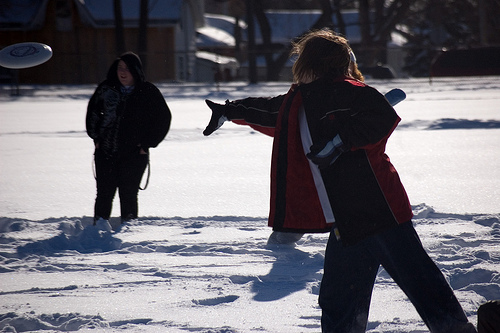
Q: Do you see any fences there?
A: No, there are no fences.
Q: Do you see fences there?
A: No, there are no fences.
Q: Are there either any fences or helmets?
A: No, there are no fences or helmets.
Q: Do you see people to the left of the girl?
A: Yes, there is a person to the left of the girl.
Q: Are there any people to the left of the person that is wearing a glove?
A: Yes, there is a person to the left of the girl.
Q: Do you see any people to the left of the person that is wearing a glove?
A: Yes, there is a person to the left of the girl.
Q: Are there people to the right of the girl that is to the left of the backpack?
A: No, the person is to the left of the girl.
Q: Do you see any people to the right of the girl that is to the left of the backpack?
A: No, the person is to the left of the girl.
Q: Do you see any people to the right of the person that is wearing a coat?
A: No, the person is to the left of the girl.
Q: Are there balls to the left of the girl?
A: No, there is a person to the left of the girl.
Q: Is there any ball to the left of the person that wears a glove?
A: No, there is a person to the left of the girl.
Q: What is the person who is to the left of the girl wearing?
A: The person is wearing trousers.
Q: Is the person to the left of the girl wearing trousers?
A: Yes, the person is wearing trousers.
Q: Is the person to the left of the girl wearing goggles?
A: No, the person is wearing trousers.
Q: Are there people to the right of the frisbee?
A: Yes, there is a person to the right of the frisbee.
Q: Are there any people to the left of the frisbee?
A: No, the person is to the right of the frisbee.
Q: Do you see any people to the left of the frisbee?
A: No, the person is to the right of the frisbee.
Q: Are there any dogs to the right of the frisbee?
A: No, there is a person to the right of the frisbee.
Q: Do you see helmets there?
A: No, there are no helmets.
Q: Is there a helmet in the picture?
A: No, there are no helmets.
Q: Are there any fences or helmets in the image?
A: No, there are no helmets or fences.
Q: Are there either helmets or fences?
A: No, there are no helmets or fences.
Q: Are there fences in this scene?
A: No, there are no fences.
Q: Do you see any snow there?
A: Yes, there is snow.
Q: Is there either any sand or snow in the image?
A: Yes, there is snow.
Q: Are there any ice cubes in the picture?
A: No, there are no ice cubes.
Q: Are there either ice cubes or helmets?
A: No, there are no ice cubes or helmets.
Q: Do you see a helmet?
A: No, there are no helmets.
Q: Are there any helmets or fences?
A: No, there are no helmets or fences.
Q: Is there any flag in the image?
A: No, there are no flags.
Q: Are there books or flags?
A: No, there are no flags or books.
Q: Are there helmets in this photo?
A: No, there are no helmets.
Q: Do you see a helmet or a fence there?
A: No, there are no helmets or fences.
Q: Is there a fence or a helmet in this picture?
A: No, there are no helmets or fences.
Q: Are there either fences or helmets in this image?
A: No, there are no helmets or fences.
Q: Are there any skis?
A: No, there are no skis.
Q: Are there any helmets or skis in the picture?
A: No, there are no skis or helmets.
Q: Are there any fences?
A: No, there are no fences.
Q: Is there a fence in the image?
A: No, there are no fences.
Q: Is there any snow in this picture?
A: Yes, there is snow.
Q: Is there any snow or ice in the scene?
A: Yes, there is snow.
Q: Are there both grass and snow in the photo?
A: No, there is snow but no grass.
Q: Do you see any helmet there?
A: No, there are no helmets.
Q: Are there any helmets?
A: No, there are no helmets.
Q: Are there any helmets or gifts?
A: No, there are no helmets or gifts.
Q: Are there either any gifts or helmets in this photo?
A: No, there are no helmets or gifts.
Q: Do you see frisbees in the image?
A: Yes, there is a frisbee.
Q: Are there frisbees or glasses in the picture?
A: Yes, there is a frisbee.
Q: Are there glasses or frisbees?
A: Yes, there is a frisbee.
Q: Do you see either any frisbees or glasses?
A: Yes, there is a frisbee.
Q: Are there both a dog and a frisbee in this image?
A: No, there is a frisbee but no dogs.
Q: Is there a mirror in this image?
A: No, there are no mirrors.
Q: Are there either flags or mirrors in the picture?
A: No, there are no mirrors or flags.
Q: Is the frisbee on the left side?
A: Yes, the frisbee is on the left of the image.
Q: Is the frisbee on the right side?
A: No, the frisbee is on the left of the image.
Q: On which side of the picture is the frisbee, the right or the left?
A: The frisbee is on the left of the image.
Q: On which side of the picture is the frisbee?
A: The frisbee is on the left of the image.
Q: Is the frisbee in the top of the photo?
A: Yes, the frisbee is in the top of the image.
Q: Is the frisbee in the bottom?
A: No, the frisbee is in the top of the image.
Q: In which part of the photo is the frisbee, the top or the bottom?
A: The frisbee is in the top of the image.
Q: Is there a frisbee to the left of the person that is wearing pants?
A: Yes, there is a frisbee to the left of the person.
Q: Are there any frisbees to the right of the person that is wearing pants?
A: No, the frisbee is to the left of the person.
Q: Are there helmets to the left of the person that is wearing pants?
A: No, there is a frisbee to the left of the person.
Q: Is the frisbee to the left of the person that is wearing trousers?
A: Yes, the frisbee is to the left of the person.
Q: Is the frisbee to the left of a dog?
A: No, the frisbee is to the left of the person.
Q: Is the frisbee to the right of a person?
A: No, the frisbee is to the left of a person.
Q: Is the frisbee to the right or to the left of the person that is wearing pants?
A: The frisbee is to the left of the person.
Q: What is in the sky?
A: The frisbee is in the sky.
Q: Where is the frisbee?
A: The frisbee is in the sky.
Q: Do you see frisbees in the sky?
A: Yes, there is a frisbee in the sky.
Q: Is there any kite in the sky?
A: No, there is a frisbee in the sky.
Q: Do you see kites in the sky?
A: No, there is a frisbee in the sky.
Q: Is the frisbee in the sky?
A: Yes, the frisbee is in the sky.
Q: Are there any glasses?
A: No, there are no glasses.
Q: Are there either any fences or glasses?
A: No, there are no glasses or fences.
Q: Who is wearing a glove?
A: The girl is wearing a glove.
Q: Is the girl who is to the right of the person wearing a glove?
A: Yes, the girl is wearing a glove.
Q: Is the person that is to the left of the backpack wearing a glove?
A: Yes, the girl is wearing a glove.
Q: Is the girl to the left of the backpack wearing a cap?
A: No, the girl is wearing a glove.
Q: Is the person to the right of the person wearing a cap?
A: No, the girl is wearing a glove.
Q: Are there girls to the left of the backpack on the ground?
A: Yes, there is a girl to the left of the backpack.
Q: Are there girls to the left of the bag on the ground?
A: Yes, there is a girl to the left of the backpack.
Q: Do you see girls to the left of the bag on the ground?
A: Yes, there is a girl to the left of the backpack.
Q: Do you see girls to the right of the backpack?
A: No, the girl is to the left of the backpack.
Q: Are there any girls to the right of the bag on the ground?
A: No, the girl is to the left of the backpack.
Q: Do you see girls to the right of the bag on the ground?
A: No, the girl is to the left of the backpack.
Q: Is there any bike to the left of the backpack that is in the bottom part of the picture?
A: No, there is a girl to the left of the backpack.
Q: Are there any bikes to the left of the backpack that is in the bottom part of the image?
A: No, there is a girl to the left of the backpack.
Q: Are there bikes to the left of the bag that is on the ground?
A: No, there is a girl to the left of the backpack.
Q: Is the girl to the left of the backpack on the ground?
A: Yes, the girl is to the left of the backpack.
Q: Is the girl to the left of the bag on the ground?
A: Yes, the girl is to the left of the backpack.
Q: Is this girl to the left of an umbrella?
A: No, the girl is to the left of the backpack.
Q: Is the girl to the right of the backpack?
A: No, the girl is to the left of the backpack.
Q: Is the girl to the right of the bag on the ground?
A: No, the girl is to the left of the backpack.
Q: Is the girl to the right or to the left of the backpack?
A: The girl is to the left of the backpack.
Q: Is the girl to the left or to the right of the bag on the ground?
A: The girl is to the left of the backpack.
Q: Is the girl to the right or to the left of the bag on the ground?
A: The girl is to the left of the backpack.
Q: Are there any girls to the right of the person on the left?
A: Yes, there is a girl to the right of the person.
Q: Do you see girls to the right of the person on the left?
A: Yes, there is a girl to the right of the person.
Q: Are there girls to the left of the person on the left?
A: No, the girl is to the right of the person.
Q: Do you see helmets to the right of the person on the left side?
A: No, there is a girl to the right of the person.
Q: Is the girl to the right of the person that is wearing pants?
A: Yes, the girl is to the right of the person.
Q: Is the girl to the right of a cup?
A: No, the girl is to the right of the person.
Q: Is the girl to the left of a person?
A: No, the girl is to the right of a person.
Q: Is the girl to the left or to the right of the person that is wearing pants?
A: The girl is to the right of the person.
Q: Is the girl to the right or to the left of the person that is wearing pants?
A: The girl is to the right of the person.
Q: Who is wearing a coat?
A: The girl is wearing a coat.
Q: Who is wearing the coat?
A: The girl is wearing a coat.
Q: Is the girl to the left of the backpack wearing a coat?
A: Yes, the girl is wearing a coat.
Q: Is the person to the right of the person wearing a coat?
A: Yes, the girl is wearing a coat.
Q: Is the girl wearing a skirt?
A: No, the girl is wearing a coat.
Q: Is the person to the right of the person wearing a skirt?
A: No, the girl is wearing a coat.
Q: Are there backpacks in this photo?
A: Yes, there is a backpack.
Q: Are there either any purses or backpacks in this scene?
A: Yes, there is a backpack.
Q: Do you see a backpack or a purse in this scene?
A: Yes, there is a backpack.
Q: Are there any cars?
A: No, there are no cars.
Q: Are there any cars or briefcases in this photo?
A: No, there are no cars or briefcases.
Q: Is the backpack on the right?
A: Yes, the backpack is on the right of the image.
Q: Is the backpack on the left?
A: No, the backpack is on the right of the image.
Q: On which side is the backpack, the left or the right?
A: The backpack is on the right of the image.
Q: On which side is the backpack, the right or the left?
A: The backpack is on the right of the image.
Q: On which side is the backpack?
A: The backpack is on the right of the image.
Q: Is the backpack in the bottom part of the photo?
A: Yes, the backpack is in the bottom of the image.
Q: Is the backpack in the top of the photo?
A: No, the backpack is in the bottom of the image.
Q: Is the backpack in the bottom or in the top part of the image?
A: The backpack is in the bottom of the image.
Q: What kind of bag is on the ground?
A: The bag is a backpack.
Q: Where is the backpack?
A: The backpack is on the ground.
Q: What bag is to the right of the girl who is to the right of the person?
A: The bag is a backpack.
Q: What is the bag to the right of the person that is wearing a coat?
A: The bag is a backpack.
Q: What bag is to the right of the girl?
A: The bag is a backpack.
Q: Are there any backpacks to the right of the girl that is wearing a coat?
A: Yes, there is a backpack to the right of the girl.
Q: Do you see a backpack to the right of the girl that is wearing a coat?
A: Yes, there is a backpack to the right of the girl.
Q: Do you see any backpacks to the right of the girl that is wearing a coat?
A: Yes, there is a backpack to the right of the girl.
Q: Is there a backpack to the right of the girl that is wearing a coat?
A: Yes, there is a backpack to the right of the girl.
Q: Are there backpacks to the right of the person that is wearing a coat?
A: Yes, there is a backpack to the right of the girl.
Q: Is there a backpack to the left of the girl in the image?
A: No, the backpack is to the right of the girl.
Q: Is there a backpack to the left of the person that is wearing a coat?
A: No, the backpack is to the right of the girl.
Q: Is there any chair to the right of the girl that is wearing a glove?
A: No, there is a backpack to the right of the girl.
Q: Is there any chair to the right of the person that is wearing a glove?
A: No, there is a backpack to the right of the girl.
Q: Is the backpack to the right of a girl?
A: Yes, the backpack is to the right of a girl.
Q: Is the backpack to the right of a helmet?
A: No, the backpack is to the right of a girl.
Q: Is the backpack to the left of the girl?
A: No, the backpack is to the right of the girl.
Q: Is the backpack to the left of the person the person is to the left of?
A: No, the backpack is to the right of the girl.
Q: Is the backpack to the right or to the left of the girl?
A: The backpack is to the right of the girl.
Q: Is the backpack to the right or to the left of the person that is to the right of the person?
A: The backpack is to the right of the girl.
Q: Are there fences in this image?
A: No, there are no fences.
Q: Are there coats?
A: Yes, there is a coat.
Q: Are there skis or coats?
A: Yes, there is a coat.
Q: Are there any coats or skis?
A: Yes, there is a coat.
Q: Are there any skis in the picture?
A: No, there are no skis.